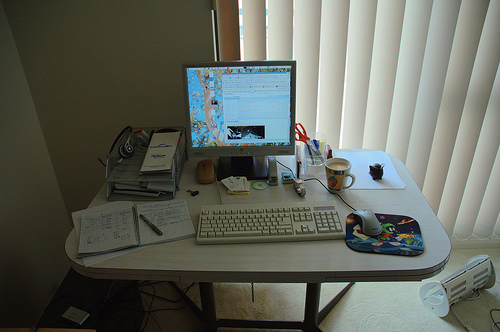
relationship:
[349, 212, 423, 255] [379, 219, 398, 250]
pad with character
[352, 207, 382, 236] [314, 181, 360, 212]
mouse with wire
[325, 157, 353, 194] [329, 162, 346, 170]
cup of coffee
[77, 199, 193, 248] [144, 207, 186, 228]
notebook with writing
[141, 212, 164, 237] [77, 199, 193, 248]
pen lying on notebook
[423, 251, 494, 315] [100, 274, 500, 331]
heater on floor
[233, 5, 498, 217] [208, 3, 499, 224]
blinds are on window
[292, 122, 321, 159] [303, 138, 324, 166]
scissors in cup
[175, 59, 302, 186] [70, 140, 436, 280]
computer on top of table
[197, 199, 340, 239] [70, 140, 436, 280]
keyboard on top of a table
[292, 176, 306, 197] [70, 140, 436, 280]
watch on top of table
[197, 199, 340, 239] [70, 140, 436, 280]
keyboard on top of table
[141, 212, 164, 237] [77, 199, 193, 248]
pen on top of notebook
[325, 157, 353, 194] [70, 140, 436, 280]
mug on top of table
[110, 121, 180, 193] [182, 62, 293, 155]
tray beside monitor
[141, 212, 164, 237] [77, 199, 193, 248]
pen on a notebook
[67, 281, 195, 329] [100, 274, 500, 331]
cords lying on floor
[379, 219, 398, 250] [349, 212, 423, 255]
marvin printed on mousepad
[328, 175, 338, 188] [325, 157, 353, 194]
strawberry on side of cup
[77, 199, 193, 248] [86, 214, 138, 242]
notebook with notes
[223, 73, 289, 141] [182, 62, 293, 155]
window on screen